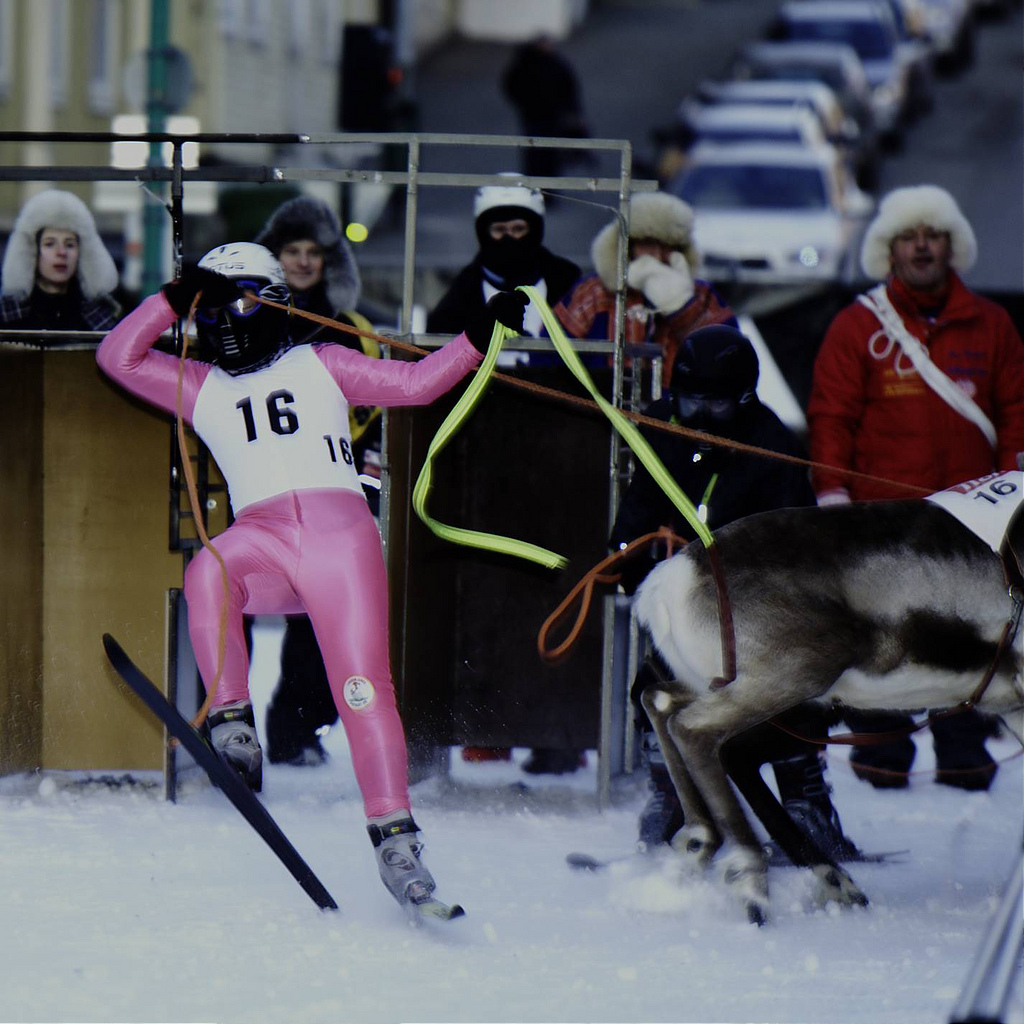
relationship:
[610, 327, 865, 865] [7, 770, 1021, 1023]
person walking on ice